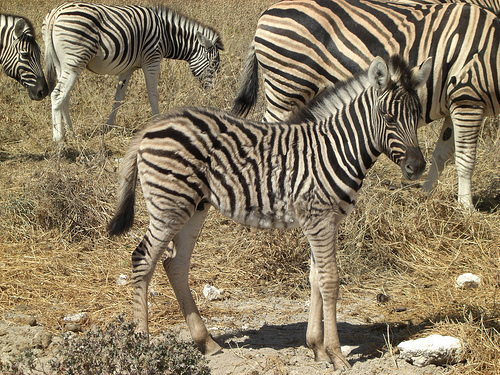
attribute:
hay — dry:
[397, 215, 437, 261]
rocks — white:
[403, 328, 464, 366]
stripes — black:
[329, 118, 362, 175]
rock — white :
[403, 332, 458, 365]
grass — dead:
[77, 125, 113, 165]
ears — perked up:
[371, 58, 434, 88]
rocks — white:
[398, 328, 463, 365]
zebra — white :
[126, 67, 446, 373]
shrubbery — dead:
[24, 315, 196, 369]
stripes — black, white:
[331, 109, 368, 159]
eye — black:
[18, 48, 30, 66]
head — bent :
[186, 31, 222, 81]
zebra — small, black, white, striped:
[114, 59, 431, 373]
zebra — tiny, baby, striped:
[104, 51, 444, 365]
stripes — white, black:
[129, 91, 381, 323]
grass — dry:
[213, 163, 497, 303]